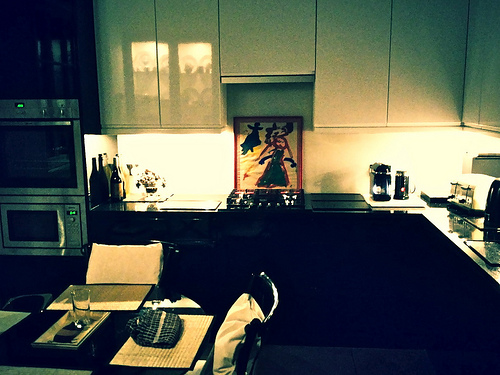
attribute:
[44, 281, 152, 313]
placemat — tan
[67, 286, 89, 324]
glass — empty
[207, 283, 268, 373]
pillow — square, white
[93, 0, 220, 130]
cabinets — shiny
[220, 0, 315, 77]
cabinets — shiny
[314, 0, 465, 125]
cabinets — shiny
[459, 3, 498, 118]
cabinets — shiny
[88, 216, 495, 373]
cabinets — dark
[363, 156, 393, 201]
coffee pot — black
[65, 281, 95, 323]
glass — empty, transparent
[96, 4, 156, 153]
cabinet — white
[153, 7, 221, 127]
cabinet — white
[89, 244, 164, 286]
white pillow — square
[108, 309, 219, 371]
place mat — rectangular, bamboo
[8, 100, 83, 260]
appliances — stainless steel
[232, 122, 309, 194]
toaster — silver, black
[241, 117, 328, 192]
art — colorful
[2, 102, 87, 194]
oven — stainless steel, elevated